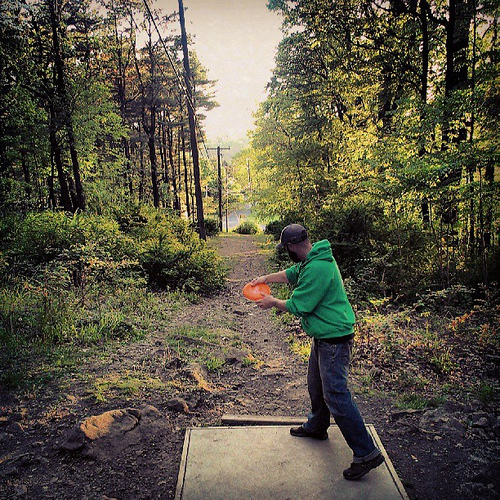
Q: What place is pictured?
A: It is a forest.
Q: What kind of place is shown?
A: It is a forest.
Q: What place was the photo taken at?
A: It was taken at the forest.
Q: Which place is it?
A: It is a forest.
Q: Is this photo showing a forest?
A: Yes, it is showing a forest.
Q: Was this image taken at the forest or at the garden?
A: It was taken at the forest.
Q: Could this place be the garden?
A: No, it is the forest.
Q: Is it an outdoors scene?
A: Yes, it is outdoors.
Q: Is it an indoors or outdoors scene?
A: It is outdoors.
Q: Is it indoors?
A: No, it is outdoors.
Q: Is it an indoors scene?
A: No, it is outdoors.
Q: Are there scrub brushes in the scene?
A: No, there are no scrub brushes.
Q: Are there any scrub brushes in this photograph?
A: No, there are no scrub brushes.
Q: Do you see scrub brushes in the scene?
A: No, there are no scrub brushes.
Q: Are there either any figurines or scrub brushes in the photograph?
A: No, there are no scrub brushes or figurines.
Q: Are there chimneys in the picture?
A: No, there are no chimneys.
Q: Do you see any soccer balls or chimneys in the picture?
A: No, there are no chimneys or soccer balls.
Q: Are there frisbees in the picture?
A: Yes, there is a frisbee.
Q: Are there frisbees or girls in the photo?
A: Yes, there is a frisbee.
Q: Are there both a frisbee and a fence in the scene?
A: No, there is a frisbee but no fences.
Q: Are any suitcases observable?
A: No, there are no suitcases.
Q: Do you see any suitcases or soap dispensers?
A: No, there are no suitcases or soap dispensers.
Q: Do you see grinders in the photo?
A: No, there are no grinders.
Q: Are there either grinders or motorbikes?
A: No, there are no grinders or motorbikes.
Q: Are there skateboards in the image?
A: No, there are no skateboards.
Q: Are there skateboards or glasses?
A: No, there are no skateboards or glasses.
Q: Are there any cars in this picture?
A: No, there are no cars.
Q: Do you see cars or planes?
A: No, there are no cars or planes.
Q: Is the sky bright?
A: Yes, the sky is bright.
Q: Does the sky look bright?
A: Yes, the sky is bright.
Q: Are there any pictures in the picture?
A: No, there are no pictures.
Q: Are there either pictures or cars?
A: No, there are no pictures or cars.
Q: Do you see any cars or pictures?
A: No, there are no pictures or cars.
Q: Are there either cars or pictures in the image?
A: No, there are no pictures or cars.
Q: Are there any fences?
A: No, there are no fences.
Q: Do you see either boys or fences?
A: No, there are no fences or boys.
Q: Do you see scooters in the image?
A: No, there are no scooters.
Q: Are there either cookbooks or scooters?
A: No, there are no scooters or cookbooks.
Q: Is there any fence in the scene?
A: No, there are no fences.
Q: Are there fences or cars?
A: No, there are no fences or cars.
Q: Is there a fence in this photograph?
A: No, there are no fences.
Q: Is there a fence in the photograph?
A: No, there are no fences.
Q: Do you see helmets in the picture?
A: No, there are no helmets.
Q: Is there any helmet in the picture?
A: No, there are no helmets.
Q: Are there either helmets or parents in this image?
A: No, there are no helmets or parents.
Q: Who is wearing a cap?
A: The man is wearing a cap.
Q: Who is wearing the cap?
A: The man is wearing a cap.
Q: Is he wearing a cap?
A: Yes, the man is wearing a cap.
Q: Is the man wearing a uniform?
A: No, the man is wearing a cap.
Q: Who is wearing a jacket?
A: The man is wearing a jacket.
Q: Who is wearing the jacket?
A: The man is wearing a jacket.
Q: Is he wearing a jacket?
A: Yes, the man is wearing a jacket.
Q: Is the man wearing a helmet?
A: No, the man is wearing a jacket.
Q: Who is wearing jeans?
A: The man is wearing jeans.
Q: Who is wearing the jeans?
A: The man is wearing jeans.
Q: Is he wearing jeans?
A: Yes, the man is wearing jeans.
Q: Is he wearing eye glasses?
A: No, the man is wearing jeans.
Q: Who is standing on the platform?
A: The man is standing on the platform.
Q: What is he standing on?
A: The man is standing on the platform.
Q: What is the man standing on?
A: The man is standing on the platform.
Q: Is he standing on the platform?
A: Yes, the man is standing on the platform.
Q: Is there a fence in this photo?
A: No, there are no fences.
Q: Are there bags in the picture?
A: No, there are no bags.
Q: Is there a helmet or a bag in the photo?
A: No, there are no bags or helmets.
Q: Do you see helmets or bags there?
A: No, there are no bags or helmets.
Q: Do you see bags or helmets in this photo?
A: No, there are no bags or helmets.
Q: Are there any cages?
A: No, there are no cages.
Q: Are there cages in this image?
A: No, there are no cages.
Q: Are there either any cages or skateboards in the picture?
A: No, there are no cages or skateboards.